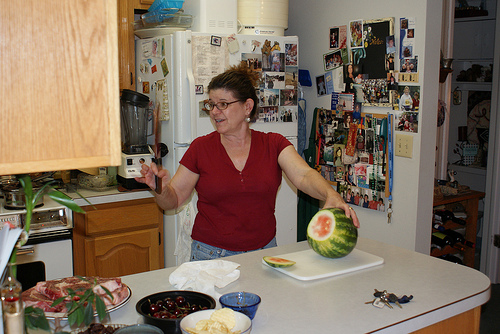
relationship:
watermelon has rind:
[303, 209, 358, 252] [263, 252, 293, 269]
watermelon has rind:
[303, 209, 358, 252] [266, 252, 294, 273]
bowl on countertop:
[223, 293, 261, 312] [99, 238, 468, 328]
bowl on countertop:
[136, 285, 211, 321] [99, 238, 468, 328]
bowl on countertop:
[179, 313, 257, 332] [99, 238, 468, 328]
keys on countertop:
[366, 283, 415, 313] [99, 238, 468, 328]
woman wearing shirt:
[134, 64, 358, 264] [178, 135, 283, 247]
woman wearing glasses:
[134, 64, 358, 264] [200, 96, 251, 109]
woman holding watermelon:
[134, 64, 358, 264] [303, 209, 358, 252]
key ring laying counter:
[366, 283, 415, 313] [106, 226, 499, 313]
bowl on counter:
[223, 293, 261, 312] [106, 226, 499, 313]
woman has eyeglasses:
[189, 72, 305, 252] [200, 96, 251, 109]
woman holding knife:
[189, 72, 305, 252] [151, 99, 166, 200]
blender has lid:
[123, 87, 156, 191] [120, 86, 158, 106]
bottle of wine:
[438, 208, 463, 227] [437, 208, 454, 221]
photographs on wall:
[319, 40, 383, 186] [286, 6, 426, 231]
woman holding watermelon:
[189, 72, 305, 252] [303, 209, 358, 252]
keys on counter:
[366, 283, 415, 313] [106, 226, 499, 313]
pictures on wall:
[319, 40, 383, 186] [286, 6, 426, 231]